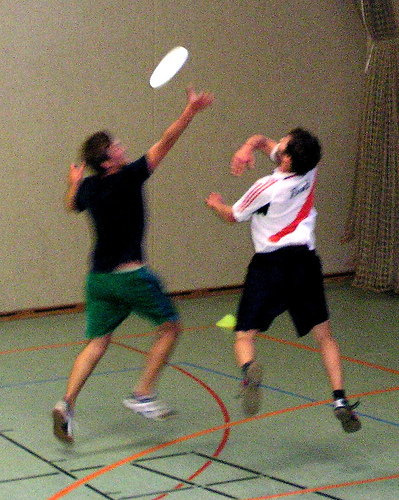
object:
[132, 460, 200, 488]
line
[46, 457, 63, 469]
line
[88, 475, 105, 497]
line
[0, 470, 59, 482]
line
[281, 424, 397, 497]
floor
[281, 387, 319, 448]
line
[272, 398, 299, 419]
line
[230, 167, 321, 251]
shirt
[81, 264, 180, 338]
shorts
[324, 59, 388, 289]
net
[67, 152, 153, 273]
shirt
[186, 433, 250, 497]
line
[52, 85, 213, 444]
guys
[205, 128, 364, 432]
guys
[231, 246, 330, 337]
shorts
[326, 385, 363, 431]
shoe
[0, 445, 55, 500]
black line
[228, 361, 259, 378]
sock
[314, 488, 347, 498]
line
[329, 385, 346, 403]
sock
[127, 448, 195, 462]
line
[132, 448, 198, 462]
line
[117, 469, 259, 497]
line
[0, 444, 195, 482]
line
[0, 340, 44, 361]
line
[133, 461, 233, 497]
line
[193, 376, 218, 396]
line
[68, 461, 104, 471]
line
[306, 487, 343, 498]
line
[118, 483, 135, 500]
line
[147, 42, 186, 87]
frisbee